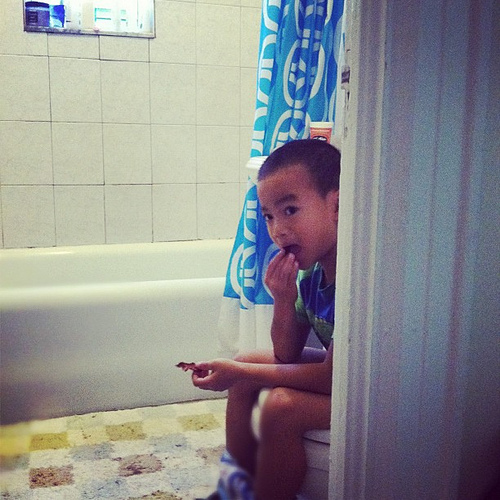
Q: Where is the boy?
A: Bathroom.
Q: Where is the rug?
A: On the ground.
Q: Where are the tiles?
A: Shower wall.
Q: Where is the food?
A: Boy's hands.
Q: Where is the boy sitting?
A: Toilet.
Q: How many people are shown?
A: 1.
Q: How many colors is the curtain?
A: 2.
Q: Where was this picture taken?
A: The bathroom.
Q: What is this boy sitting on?
A: Toilet.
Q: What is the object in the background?
A: A bathtub.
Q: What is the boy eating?
A: Bacon.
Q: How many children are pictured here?
A: One.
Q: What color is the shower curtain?
A: Blue and white.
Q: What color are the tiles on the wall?
A: White.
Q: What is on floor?
A: Checkered bath mat.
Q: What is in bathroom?
A: White bathtub.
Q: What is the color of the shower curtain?
A: Blue and white.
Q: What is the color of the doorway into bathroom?
A: White.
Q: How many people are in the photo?
A: One.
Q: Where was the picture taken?
A: In a bathroom.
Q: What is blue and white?
A: Shower curtain.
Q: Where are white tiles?
A: On the wall.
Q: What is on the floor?
A: A rug.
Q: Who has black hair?
A: A boy.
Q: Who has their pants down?
A: The boy.